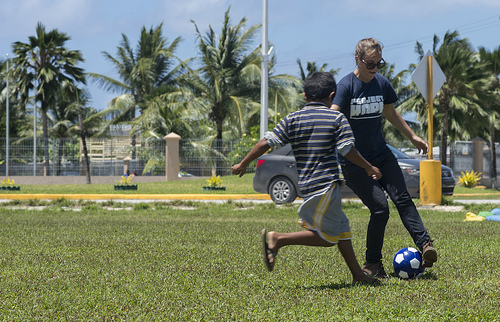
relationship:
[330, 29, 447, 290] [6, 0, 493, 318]
man playing soccer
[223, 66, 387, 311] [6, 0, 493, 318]
boy playing soccer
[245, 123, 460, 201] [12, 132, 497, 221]
car in lot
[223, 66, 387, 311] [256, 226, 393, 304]
boy wearing sandals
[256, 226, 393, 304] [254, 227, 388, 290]
sandals on feet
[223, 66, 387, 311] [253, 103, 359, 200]
boy in shirt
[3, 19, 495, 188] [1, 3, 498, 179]
trees in background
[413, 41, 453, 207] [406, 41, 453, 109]
post holding sign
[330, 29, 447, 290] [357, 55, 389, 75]
man wearing sunglasses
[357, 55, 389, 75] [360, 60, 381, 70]
sunglasses over eyes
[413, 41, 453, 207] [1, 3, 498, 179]
post in background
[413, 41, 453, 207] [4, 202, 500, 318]
post in field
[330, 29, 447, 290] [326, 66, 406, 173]
man in shirt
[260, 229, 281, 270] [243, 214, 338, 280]
feet in air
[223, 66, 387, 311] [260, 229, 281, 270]
boy has feet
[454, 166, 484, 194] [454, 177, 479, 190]
flowers in pot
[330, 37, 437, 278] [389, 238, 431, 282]
man kicking ball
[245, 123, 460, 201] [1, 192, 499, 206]
car by curb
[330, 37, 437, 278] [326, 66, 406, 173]
man has shirt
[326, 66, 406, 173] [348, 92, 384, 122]
shirt has writing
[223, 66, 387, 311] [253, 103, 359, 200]
boy has shirt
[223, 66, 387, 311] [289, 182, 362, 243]
boy has shorts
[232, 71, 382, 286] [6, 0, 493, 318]
boy playing soccer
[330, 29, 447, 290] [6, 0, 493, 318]
adult playing soccer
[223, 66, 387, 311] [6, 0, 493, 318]
child playing soccer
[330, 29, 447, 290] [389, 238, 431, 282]
adult kicking ball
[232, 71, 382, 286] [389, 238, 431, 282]
boy kicking ball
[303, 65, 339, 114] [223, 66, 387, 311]
head of boy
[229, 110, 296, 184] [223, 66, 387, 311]
arm of boy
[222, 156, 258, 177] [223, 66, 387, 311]
hand of boy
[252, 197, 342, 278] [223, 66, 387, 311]
leg of boy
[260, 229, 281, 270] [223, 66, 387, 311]
feet of boy